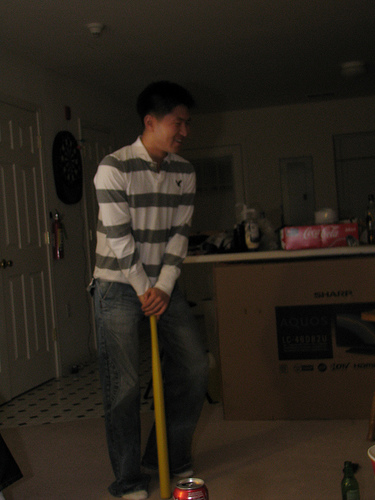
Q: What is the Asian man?
A: The man is tall.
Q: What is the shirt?
A: Long sleeved.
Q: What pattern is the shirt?
A: Stripe.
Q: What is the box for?
A: Television.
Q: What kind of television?
A: Flat screen.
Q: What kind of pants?
A: Jeans.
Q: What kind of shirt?
A: Long sleeve.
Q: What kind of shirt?
A: Long sleeve.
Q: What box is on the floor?
A: Television box.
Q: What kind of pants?
A: Jeans.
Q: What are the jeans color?
A: Blue.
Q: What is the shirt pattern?
A: Stripe.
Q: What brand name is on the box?
A: Sharp.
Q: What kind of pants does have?
A: Blue jeans.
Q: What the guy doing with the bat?
A: Leaning.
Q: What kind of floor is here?
A: Carpet.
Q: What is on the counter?
A: Coke.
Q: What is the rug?
A: Carpeted.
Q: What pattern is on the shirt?
A: Striped.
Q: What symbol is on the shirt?
A: An eagle.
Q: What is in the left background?
A: Door.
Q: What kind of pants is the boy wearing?
A: Jeans.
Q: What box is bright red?
A: Soda box.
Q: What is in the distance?
A: A television box.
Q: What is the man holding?
A: A yellow stick.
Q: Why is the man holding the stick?
A: To support himself.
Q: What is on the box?
A: A case of Coca-Cola.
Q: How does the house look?
A: Messy.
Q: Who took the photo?
A: Jack.